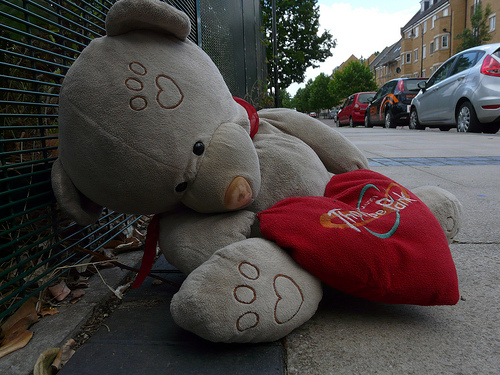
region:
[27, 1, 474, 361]
teddy bear on the street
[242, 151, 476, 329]
a heart color red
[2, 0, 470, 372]
teddy bear in front a metal door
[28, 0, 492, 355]
teddy bear abandoned in the street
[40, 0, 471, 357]
teddy bear on sidewalk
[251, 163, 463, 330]
red toy heart next to teddy bear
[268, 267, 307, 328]
heart shape sewn on bottom of teddy bear feet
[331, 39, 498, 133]
line of cars parked next to sidewalk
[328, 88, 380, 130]
red car parked next to sidewalk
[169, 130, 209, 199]
eyes of stuffed teddy bear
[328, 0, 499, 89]
buildings lining sidewalk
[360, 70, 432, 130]
black and red car parked next to sidewalk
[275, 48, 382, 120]
tall green trees lining sidewalk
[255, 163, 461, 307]
A red heart on a bear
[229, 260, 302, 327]
Pawprints on a stuffed bear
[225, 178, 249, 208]
A light brown nose on a stuffed bear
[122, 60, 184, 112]
A paw print on a stuffed bear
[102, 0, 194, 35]
An ear on a stuffed bear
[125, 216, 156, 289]
A ribbon on a stuffed bear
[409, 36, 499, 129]
A gray car on a street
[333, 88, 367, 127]
A red car on a street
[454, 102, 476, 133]
A black tire on a car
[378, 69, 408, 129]
a vehicle on teh road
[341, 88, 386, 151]
a vehicle on teh road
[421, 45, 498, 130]
a vehicle on teh street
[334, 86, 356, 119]
a vehicle on teh street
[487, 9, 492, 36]
a window on a building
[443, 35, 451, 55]
a window on a building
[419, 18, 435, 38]
a window on a building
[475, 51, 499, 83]
brake light on back of silver car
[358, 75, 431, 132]
black and red car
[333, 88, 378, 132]
red car parked next to sidewalk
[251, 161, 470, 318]
heart shape sewn into bottom paw of stuffed teddybear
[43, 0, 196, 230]
two stuffed teddy bear ears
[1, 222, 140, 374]
leaves on side of sidewalk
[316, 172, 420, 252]
company logo on front of red stuffed hear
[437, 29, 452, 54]
window on front of building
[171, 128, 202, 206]
black stuffed teddy bear eyes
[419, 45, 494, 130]
this is a car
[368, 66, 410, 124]
this is a car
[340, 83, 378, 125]
this is a car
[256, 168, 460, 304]
the heart is red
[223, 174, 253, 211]
the nose is brown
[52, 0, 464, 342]
the teddy bear is large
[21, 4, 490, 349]
Teddy bear on the ground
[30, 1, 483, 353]
Teddy bear on the sidewalk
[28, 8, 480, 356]
Teddy bear on the asphalt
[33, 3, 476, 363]
Teddy bear on the concrete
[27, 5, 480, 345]
Brown teddy bear on the ground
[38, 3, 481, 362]
Brown teddy bear on the sidewalk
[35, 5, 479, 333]
Brown teddy bear near the street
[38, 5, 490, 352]
Teddy bear near the street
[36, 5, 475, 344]
Teddy bear near the cars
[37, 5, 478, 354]
Teddy bear with paw print on its head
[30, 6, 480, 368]
bear on the side walk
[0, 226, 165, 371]
debris on the ground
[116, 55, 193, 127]
paw print on bear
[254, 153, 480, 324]
a red plush heart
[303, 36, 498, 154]
a row of cars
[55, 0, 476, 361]
the bear is brown